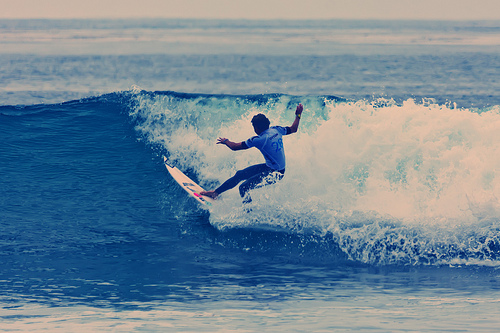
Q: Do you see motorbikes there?
A: No, there are no motorbikes.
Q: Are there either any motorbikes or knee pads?
A: No, there are no motorbikes or knee pads.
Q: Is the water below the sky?
A: Yes, the water is below the sky.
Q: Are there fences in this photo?
A: No, there are no fences.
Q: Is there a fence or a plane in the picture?
A: No, there are no fences or airplanes.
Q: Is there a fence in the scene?
A: No, there are no fences.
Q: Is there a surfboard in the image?
A: Yes, there is a surfboard.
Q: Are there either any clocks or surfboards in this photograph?
A: Yes, there is a surfboard.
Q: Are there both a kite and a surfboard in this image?
A: No, there is a surfboard but no kites.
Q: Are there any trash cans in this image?
A: No, there are no trash cans.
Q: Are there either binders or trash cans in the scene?
A: No, there are no trash cans or binders.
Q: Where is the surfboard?
A: The surfboard is in the water.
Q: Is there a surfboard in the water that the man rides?
A: Yes, there is a surfboard in the water.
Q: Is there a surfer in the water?
A: No, there is a surfboard in the water.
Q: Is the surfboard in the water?
A: Yes, the surfboard is in the water.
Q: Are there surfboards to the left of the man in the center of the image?
A: Yes, there is a surfboard to the left of the man.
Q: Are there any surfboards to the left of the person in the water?
A: Yes, there is a surfboard to the left of the man.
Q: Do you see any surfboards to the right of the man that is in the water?
A: No, the surfboard is to the left of the man.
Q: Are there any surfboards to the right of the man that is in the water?
A: No, the surfboard is to the left of the man.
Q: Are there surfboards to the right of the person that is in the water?
A: No, the surfboard is to the left of the man.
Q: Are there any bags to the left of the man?
A: No, there is a surfboard to the left of the man.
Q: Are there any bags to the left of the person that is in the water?
A: No, there is a surfboard to the left of the man.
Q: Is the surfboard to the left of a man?
A: Yes, the surfboard is to the left of a man.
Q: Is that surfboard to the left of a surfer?
A: No, the surfboard is to the left of a man.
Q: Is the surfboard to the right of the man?
A: No, the surfboard is to the left of the man.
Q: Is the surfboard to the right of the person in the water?
A: No, the surfboard is to the left of the man.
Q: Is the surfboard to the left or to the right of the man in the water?
A: The surfboard is to the left of the man.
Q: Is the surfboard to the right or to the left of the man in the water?
A: The surfboard is to the left of the man.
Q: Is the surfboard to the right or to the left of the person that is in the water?
A: The surfboard is to the left of the man.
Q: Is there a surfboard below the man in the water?
A: Yes, there is a surfboard below the man.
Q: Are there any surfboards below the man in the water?
A: Yes, there is a surfboard below the man.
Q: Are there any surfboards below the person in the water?
A: Yes, there is a surfboard below the man.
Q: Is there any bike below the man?
A: No, there is a surfboard below the man.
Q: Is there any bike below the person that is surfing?
A: No, there is a surfboard below the man.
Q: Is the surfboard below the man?
A: Yes, the surfboard is below the man.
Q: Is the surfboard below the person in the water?
A: Yes, the surfboard is below the man.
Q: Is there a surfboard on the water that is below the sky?
A: Yes, there is a surfboard on the water.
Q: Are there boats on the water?
A: No, there is a surfboard on the water.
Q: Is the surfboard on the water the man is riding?
A: Yes, the surfboard is on the water.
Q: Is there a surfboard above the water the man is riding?
A: Yes, there is a surfboard above the water.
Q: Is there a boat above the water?
A: No, there is a surfboard above the water.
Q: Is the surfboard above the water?
A: Yes, the surfboard is above the water.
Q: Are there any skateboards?
A: No, there are no skateboards.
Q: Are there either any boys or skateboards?
A: No, there are no skateboards or boys.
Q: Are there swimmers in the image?
A: No, there are no swimmers.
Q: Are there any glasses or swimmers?
A: No, there are no swimmers or glasses.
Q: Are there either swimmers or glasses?
A: No, there are no swimmers or glasses.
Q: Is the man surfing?
A: Yes, the man is surfing.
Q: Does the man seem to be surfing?
A: Yes, the man is surfing.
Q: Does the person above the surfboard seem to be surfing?
A: Yes, the man is surfing.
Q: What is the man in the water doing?
A: The man is surfing.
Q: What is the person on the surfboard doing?
A: The man is surfing.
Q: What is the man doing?
A: The man is surfing.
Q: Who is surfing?
A: The man is surfing.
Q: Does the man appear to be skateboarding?
A: No, the man is surfing.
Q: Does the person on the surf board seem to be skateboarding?
A: No, the man is surfing.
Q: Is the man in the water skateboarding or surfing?
A: The man is surfing.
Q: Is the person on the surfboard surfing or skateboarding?
A: The man is surfing.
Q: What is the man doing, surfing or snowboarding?
A: The man is surfing.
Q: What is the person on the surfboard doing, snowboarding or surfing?
A: The man is surfing.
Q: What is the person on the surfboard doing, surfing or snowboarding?
A: The man is surfing.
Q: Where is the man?
A: The man is in the water.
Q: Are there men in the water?
A: Yes, there is a man in the water.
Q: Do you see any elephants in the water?
A: No, there is a man in the water.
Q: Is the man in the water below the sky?
A: Yes, the man is in the water.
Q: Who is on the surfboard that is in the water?
A: The man is on the surfboard.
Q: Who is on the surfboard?
A: The man is on the surfboard.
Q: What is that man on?
A: The man is on the surfboard.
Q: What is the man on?
A: The man is on the surfboard.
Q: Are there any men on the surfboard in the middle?
A: Yes, there is a man on the surfboard.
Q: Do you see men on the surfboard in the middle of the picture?
A: Yes, there is a man on the surfboard.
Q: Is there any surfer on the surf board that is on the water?
A: No, there is a man on the surfboard.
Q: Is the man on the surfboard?
A: Yes, the man is on the surfboard.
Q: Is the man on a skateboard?
A: No, the man is on the surfboard.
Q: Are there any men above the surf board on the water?
A: Yes, there is a man above the surfboard.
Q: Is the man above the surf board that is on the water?
A: Yes, the man is above the surfboard.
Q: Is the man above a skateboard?
A: No, the man is above the surfboard.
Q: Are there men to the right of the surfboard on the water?
A: Yes, there is a man to the right of the surf board.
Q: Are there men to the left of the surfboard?
A: No, the man is to the right of the surfboard.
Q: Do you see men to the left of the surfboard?
A: No, the man is to the right of the surfboard.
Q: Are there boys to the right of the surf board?
A: No, there is a man to the right of the surf board.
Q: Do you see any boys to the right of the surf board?
A: No, there is a man to the right of the surf board.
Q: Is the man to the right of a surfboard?
A: Yes, the man is to the right of a surfboard.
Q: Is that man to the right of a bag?
A: No, the man is to the right of a surfboard.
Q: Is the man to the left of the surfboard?
A: No, the man is to the right of the surfboard.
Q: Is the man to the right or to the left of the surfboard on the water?
A: The man is to the right of the surfboard.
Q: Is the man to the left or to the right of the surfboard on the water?
A: The man is to the right of the surfboard.